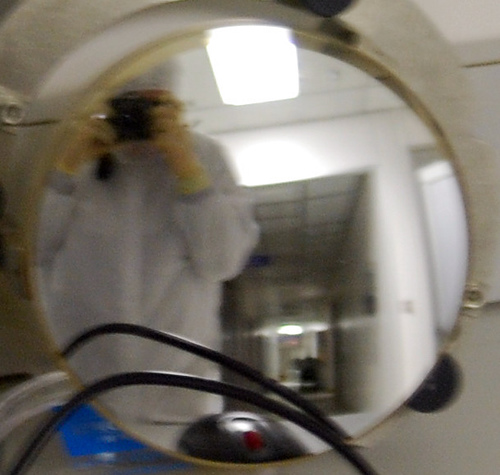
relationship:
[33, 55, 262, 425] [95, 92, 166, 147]
person holding camera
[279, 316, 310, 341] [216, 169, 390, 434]
light at end of hallway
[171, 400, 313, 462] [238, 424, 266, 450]
mouse has red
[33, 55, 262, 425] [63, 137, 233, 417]
person wearing white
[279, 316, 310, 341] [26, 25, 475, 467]
light reflecting in mirror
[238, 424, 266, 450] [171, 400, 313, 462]
red on mouse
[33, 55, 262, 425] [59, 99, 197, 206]
person wearing gloves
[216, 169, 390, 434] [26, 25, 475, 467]
hallway reflecting in mirror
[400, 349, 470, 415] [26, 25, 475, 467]
circle behind mirror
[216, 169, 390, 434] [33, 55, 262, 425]
hallway behind person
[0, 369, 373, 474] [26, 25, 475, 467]
wire in front of mirror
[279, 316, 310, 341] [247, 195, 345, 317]
light on ceiling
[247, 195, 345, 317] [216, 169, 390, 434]
ceiling in hallway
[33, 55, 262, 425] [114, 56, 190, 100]
person wearing a cap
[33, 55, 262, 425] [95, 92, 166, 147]
person taking a picture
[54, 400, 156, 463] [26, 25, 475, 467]
item behind mirror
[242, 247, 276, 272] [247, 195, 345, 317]
sign hanging from ceiling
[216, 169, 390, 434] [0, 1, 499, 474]
hallway in a lab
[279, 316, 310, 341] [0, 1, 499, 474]
light in lab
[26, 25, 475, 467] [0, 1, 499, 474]
mirror in a lab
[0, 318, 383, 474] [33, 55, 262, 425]
wires in front of person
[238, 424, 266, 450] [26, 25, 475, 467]
red reflecting on mirror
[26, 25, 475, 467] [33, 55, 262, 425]
mirror in front of person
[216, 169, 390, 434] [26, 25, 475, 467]
hallway reflected in mirror